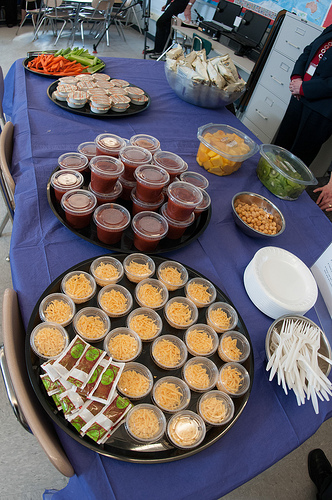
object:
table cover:
[1, 50, 330, 497]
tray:
[25, 251, 256, 464]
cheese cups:
[27, 252, 251, 452]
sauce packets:
[40, 334, 133, 447]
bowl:
[265, 312, 331, 383]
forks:
[264, 317, 331, 416]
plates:
[243, 245, 318, 320]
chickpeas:
[233, 197, 280, 235]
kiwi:
[258, 154, 303, 200]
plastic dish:
[259, 143, 317, 201]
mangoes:
[195, 130, 250, 176]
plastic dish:
[196, 122, 258, 175]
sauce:
[51, 130, 211, 255]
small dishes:
[50, 130, 212, 254]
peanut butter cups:
[55, 70, 147, 117]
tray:
[46, 73, 151, 118]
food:
[25, 44, 308, 449]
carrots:
[22, 53, 88, 74]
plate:
[22, 51, 106, 76]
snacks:
[164, 43, 248, 107]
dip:
[51, 72, 147, 116]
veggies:
[26, 47, 104, 77]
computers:
[199, 0, 272, 50]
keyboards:
[200, 17, 258, 47]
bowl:
[164, 58, 248, 106]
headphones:
[214, 1, 256, 25]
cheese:
[130, 314, 157, 337]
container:
[128, 306, 162, 339]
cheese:
[153, 340, 181, 366]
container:
[153, 336, 189, 368]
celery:
[57, 47, 104, 74]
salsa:
[90, 160, 119, 191]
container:
[90, 154, 125, 193]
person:
[270, 24, 331, 163]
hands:
[289, 79, 303, 95]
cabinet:
[240, 10, 329, 147]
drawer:
[272, 11, 322, 62]